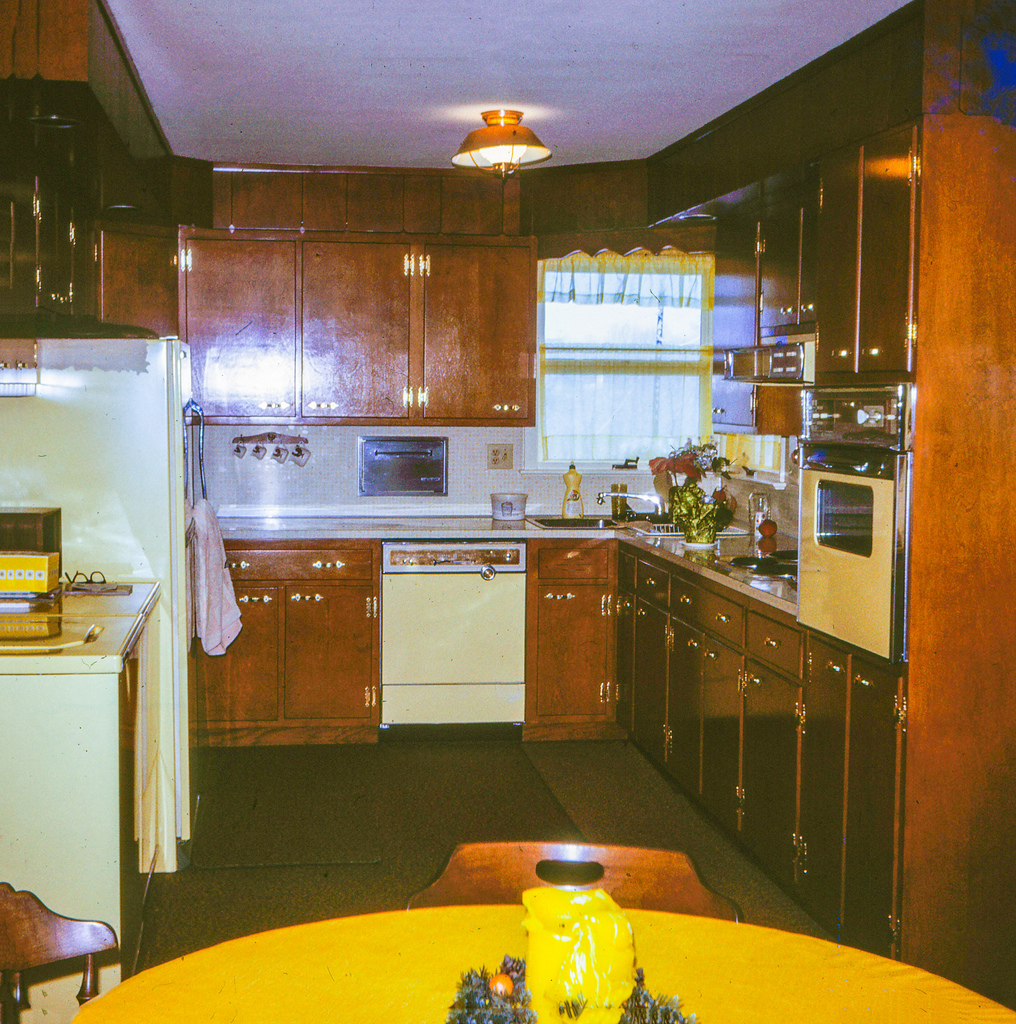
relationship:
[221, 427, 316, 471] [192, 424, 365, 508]
cup holder on wall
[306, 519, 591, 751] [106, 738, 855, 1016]
oven above ground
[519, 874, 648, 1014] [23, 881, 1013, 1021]
candle on table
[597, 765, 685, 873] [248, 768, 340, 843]
person eating orange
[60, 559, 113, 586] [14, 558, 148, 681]
glasses on counter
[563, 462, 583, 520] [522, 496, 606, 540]
bottle on sink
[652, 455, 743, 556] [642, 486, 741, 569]
red plants in pots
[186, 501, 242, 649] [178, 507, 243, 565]
kitchen towel hangiing off refrigerator handle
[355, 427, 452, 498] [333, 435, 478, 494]
door in wall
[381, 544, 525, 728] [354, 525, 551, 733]
oven in cabinets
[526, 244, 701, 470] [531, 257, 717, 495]
curtains covering window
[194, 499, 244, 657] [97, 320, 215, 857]
kitchen towel hanging on refrigerator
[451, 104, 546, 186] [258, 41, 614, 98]
light hanging on ceiling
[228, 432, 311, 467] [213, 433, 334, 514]
cup holder on wall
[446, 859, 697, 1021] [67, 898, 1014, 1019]
item on table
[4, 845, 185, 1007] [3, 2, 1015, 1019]
chair in kitchen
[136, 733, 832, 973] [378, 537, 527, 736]
ground under oven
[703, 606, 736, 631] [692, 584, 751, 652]
handle on drawer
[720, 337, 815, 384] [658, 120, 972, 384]
stove hood under cabinets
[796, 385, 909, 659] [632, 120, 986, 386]
oven under cabinets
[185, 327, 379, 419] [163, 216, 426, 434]
light shining on cabinet doors